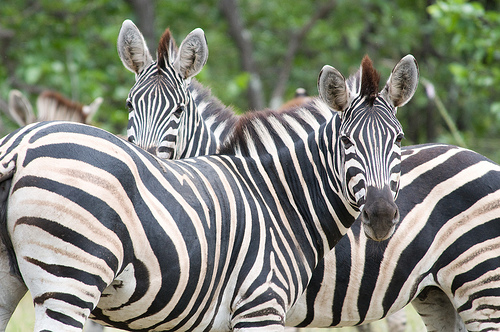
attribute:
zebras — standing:
[2, 20, 499, 331]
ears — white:
[116, 20, 211, 84]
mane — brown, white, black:
[35, 87, 86, 122]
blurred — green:
[2, 0, 499, 158]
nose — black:
[364, 209, 399, 223]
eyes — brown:
[339, 133, 404, 150]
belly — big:
[98, 266, 240, 329]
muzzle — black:
[363, 188, 399, 242]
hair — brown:
[353, 57, 384, 103]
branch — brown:
[216, 3, 334, 108]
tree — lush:
[179, 9, 471, 132]